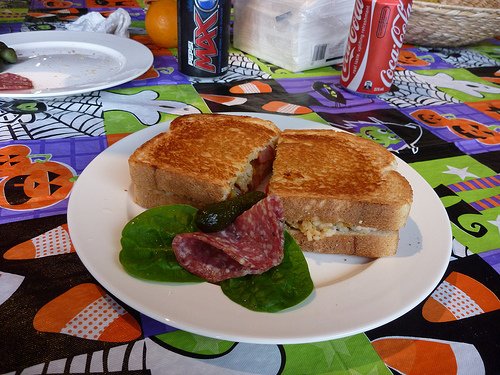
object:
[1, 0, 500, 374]
cloth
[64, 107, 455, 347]
plate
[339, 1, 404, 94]
can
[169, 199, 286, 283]
meat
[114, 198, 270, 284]
leaf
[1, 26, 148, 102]
plate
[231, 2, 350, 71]
napkins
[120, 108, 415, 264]
sandwich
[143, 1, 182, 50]
fruit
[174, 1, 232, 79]
can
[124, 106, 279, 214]
half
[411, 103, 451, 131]
pumpkin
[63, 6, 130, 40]
napkin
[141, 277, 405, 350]
edge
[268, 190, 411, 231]
edge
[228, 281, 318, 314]
edge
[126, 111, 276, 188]
surface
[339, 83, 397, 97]
base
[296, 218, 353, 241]
fat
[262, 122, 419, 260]
half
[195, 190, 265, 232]
pickle